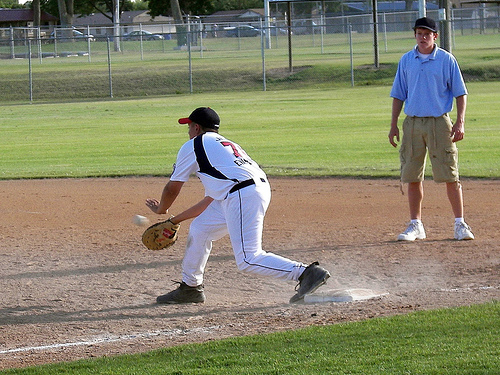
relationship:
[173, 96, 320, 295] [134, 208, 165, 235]
player catching ball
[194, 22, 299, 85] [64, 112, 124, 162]
fence on field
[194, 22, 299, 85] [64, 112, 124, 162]
fence near field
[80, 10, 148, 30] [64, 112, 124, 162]
houses near field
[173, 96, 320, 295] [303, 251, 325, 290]
player wearing shoes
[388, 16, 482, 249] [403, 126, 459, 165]
coach wearing shorts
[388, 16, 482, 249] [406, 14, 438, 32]
coach wearing hat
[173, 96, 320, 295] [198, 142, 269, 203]
player in uniform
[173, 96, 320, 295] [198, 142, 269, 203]
player with uniform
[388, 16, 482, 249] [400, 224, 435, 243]
coach wearing shoes